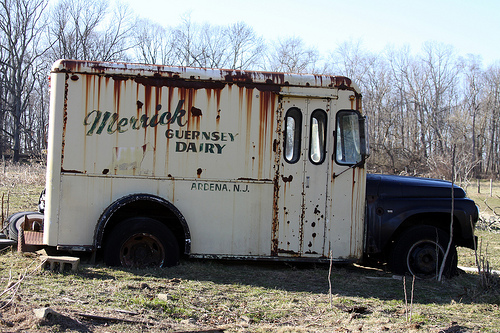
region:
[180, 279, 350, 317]
some grass on the ground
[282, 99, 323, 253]
the white truck door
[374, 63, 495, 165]
some trees in the background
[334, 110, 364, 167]
the rearview mirror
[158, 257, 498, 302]
the shadow of the truck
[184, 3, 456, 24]
a blue sky in the background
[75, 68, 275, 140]
this area is oxidized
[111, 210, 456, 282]
two tires deflated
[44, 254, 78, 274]
a block on the ground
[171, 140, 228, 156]
the word DAIRY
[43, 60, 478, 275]
antique truck stuck in the mud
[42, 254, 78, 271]
gray cinder block by back of truck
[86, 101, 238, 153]
Merrick logo on side of truck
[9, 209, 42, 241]
tire on the ground behind the truck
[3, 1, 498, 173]
several trees on the horizon behind the truck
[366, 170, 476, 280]
the truck's black front-end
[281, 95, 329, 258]
a door with two windows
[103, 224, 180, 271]
rear wheels partially buried in the mud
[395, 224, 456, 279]
front tire stuck in the mud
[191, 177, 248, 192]
Ardena, NJ painted in green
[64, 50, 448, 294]
white truck on ground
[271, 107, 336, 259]
white doors on truck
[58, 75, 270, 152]
brown rust on truck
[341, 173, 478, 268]
front of truck is black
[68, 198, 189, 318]
black tire on truck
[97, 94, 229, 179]
dark blue letters on truck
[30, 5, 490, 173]
bare trees behind truck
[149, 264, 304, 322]
green grass near truck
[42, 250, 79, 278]
grey bricks on ground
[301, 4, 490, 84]
sky is blue and bright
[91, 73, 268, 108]
rust on white truck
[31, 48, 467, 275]
an old fashioned milk truck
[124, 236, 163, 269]
a rusty tire well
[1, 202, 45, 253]
a pile of junk on the ground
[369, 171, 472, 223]
a black hood and fender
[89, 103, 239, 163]
black lettering on the side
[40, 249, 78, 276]
a gray cement block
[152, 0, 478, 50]
a cloudy white sky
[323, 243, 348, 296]
a stick in the ground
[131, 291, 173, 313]
a small patch of green grass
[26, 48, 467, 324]
truck on the ground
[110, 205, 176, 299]
rear tire of truck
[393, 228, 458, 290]
front tire of truck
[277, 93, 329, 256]
doors of the truck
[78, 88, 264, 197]
lettering on side of truck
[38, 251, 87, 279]
brick on the ground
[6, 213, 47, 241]
tire on the ground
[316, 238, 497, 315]
branches on the ground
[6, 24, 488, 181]
trees with no leaves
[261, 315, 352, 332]
bare patch on ground